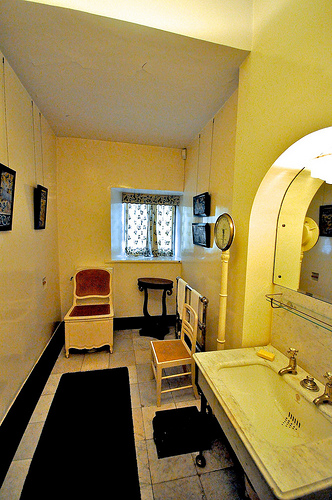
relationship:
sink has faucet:
[178, 341, 331, 493] [276, 341, 328, 420]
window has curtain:
[107, 182, 184, 264] [121, 195, 176, 259]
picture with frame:
[1, 164, 19, 232] [2, 160, 18, 238]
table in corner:
[130, 269, 170, 340] [130, 233, 186, 342]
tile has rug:
[124, 356, 160, 498] [28, 365, 138, 498]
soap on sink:
[250, 350, 282, 366] [178, 341, 331, 493]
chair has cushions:
[64, 267, 119, 362] [76, 265, 107, 321]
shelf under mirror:
[266, 295, 330, 341] [267, 152, 331, 311]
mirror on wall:
[267, 152, 331, 311] [224, 78, 328, 395]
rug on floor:
[28, 365, 138, 498] [0, 299, 197, 499]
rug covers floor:
[28, 365, 138, 498] [0, 299, 197, 499]